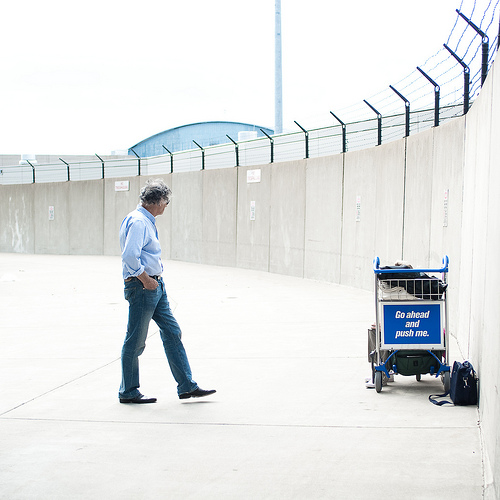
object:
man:
[114, 180, 218, 409]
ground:
[4, 258, 411, 495]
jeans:
[115, 275, 197, 405]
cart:
[368, 260, 458, 395]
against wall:
[288, 144, 490, 348]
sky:
[13, 15, 357, 118]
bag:
[448, 359, 479, 404]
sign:
[379, 305, 447, 347]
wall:
[1, 142, 499, 296]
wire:
[0, 109, 468, 171]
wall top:
[7, 165, 291, 189]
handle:
[372, 261, 454, 280]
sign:
[243, 169, 264, 186]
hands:
[129, 272, 165, 293]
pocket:
[139, 280, 164, 301]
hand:
[141, 277, 157, 292]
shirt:
[117, 203, 164, 283]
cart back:
[378, 279, 447, 354]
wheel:
[368, 367, 383, 394]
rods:
[90, 150, 106, 181]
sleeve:
[121, 218, 150, 281]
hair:
[141, 181, 170, 211]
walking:
[81, 268, 225, 422]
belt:
[126, 273, 171, 285]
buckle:
[155, 273, 165, 287]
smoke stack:
[266, 5, 290, 133]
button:
[154, 260, 164, 278]